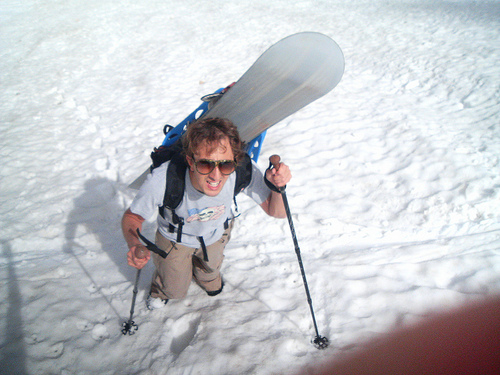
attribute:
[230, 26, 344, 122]
snowboard — grey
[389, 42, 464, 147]
snow — white